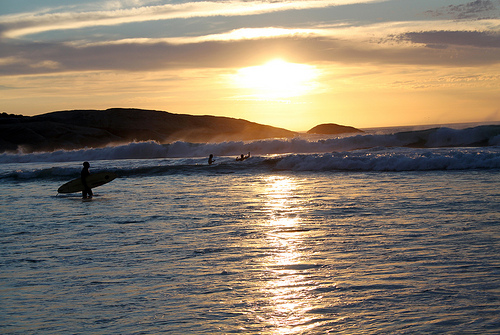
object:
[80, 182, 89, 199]
leg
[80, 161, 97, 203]
man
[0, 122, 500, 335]
ocean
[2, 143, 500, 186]
wave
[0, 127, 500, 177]
shore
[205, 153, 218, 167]
person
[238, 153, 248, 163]
person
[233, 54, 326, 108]
sun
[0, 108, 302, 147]
hill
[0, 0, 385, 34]
cloud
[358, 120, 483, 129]
water line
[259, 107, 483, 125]
horizon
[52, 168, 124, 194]
board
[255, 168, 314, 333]
sun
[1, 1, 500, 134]
sky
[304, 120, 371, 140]
mountain